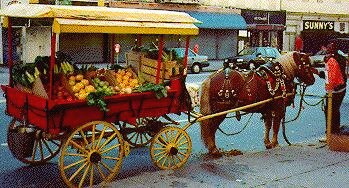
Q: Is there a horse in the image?
A: Yes, there is a horse.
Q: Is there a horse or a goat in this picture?
A: Yes, there is a horse.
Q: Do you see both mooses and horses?
A: No, there is a horse but no mooses.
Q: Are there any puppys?
A: No, there are no puppys.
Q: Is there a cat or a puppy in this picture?
A: No, there are no puppys or cats.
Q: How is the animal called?
A: The animal is a horse.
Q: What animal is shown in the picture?
A: The animal is a horse.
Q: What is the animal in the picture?
A: The animal is a horse.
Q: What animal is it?
A: The animal is a horse.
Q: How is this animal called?
A: This is a horse.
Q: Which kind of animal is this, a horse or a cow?
A: This is a horse.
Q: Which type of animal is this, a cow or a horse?
A: This is a horse.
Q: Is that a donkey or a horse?
A: That is a horse.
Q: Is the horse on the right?
A: Yes, the horse is on the right of the image.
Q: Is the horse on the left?
A: No, the horse is on the right of the image.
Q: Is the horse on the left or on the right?
A: The horse is on the right of the image.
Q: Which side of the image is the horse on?
A: The horse is on the right of the image.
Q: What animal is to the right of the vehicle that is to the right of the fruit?
A: The animal is a horse.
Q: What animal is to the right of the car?
A: The animal is a horse.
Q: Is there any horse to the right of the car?
A: Yes, there is a horse to the right of the car.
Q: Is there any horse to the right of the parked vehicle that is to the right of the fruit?
A: Yes, there is a horse to the right of the car.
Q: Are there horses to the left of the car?
A: No, the horse is to the right of the car.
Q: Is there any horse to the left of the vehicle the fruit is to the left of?
A: No, the horse is to the right of the car.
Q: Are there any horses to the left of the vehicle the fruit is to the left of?
A: No, the horse is to the right of the car.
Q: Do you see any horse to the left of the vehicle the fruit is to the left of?
A: No, the horse is to the right of the car.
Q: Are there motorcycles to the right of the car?
A: No, there is a horse to the right of the car.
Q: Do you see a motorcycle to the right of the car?
A: No, there is a horse to the right of the car.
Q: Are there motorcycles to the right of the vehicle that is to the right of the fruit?
A: No, there is a horse to the right of the car.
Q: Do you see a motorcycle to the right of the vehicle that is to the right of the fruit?
A: No, there is a horse to the right of the car.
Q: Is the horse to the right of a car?
A: Yes, the horse is to the right of a car.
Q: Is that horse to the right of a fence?
A: No, the horse is to the right of a car.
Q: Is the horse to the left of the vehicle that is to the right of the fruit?
A: No, the horse is to the right of the car.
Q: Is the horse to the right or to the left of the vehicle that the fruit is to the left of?
A: The horse is to the right of the car.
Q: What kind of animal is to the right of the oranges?
A: The animal is a horse.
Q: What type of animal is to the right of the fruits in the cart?
A: The animal is a horse.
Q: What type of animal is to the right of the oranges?
A: The animal is a horse.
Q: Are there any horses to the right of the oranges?
A: Yes, there is a horse to the right of the oranges.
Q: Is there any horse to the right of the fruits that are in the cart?
A: Yes, there is a horse to the right of the oranges.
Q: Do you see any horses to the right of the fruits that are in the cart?
A: Yes, there is a horse to the right of the oranges.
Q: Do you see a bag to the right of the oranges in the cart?
A: No, there is a horse to the right of the oranges.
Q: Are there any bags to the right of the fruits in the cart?
A: No, there is a horse to the right of the oranges.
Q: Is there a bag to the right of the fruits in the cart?
A: No, there is a horse to the right of the oranges.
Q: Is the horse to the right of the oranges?
A: Yes, the horse is to the right of the oranges.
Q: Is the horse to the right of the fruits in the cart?
A: Yes, the horse is to the right of the oranges.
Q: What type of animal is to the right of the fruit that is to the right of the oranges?
A: The animal is a horse.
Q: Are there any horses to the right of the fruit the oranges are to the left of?
A: Yes, there is a horse to the right of the fruit.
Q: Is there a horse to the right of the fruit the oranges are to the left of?
A: Yes, there is a horse to the right of the fruit.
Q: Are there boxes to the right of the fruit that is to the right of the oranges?
A: No, there is a horse to the right of the fruit.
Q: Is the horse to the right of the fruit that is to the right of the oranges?
A: Yes, the horse is to the right of the fruit.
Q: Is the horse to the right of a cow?
A: No, the horse is to the right of the fruit.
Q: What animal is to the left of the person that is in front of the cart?
A: The animal is a horse.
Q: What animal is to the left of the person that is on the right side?
A: The animal is a horse.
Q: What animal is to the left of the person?
A: The animal is a horse.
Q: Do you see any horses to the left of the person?
A: Yes, there is a horse to the left of the person.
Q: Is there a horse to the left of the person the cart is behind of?
A: Yes, there is a horse to the left of the person.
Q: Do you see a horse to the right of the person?
A: No, the horse is to the left of the person.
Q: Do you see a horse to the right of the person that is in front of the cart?
A: No, the horse is to the left of the person.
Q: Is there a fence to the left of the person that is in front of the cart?
A: No, there is a horse to the left of the person.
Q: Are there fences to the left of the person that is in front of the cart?
A: No, there is a horse to the left of the person.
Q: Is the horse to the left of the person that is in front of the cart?
A: Yes, the horse is to the left of the person.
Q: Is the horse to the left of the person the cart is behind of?
A: Yes, the horse is to the left of the person.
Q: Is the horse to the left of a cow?
A: No, the horse is to the left of the person.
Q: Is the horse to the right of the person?
A: No, the horse is to the left of the person.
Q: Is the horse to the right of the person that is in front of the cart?
A: No, the horse is to the left of the person.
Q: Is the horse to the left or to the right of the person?
A: The horse is to the left of the person.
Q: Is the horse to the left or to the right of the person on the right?
A: The horse is to the left of the person.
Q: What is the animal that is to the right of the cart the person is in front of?
A: The animal is a horse.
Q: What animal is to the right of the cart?
A: The animal is a horse.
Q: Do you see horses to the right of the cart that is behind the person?
A: Yes, there is a horse to the right of the cart.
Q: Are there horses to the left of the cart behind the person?
A: No, the horse is to the right of the cart.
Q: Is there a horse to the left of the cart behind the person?
A: No, the horse is to the right of the cart.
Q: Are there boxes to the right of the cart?
A: No, there is a horse to the right of the cart.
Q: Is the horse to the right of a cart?
A: Yes, the horse is to the right of a cart.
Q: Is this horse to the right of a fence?
A: No, the horse is to the right of a cart.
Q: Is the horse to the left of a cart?
A: No, the horse is to the right of a cart.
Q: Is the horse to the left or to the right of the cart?
A: The horse is to the right of the cart.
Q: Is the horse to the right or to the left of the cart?
A: The horse is to the right of the cart.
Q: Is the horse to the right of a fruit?
A: Yes, the horse is to the right of a fruit.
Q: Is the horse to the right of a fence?
A: No, the horse is to the right of a fruit.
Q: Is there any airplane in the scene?
A: No, there are no airplanes.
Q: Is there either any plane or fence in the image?
A: No, there are no airplanes or fences.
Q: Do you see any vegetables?
A: Yes, there are vegetables.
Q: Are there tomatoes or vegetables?
A: Yes, there are vegetables.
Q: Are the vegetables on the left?
A: Yes, the vegetables are on the left of the image.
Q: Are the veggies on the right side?
A: No, the veggies are on the left of the image.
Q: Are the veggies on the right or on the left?
A: The veggies are on the left of the image.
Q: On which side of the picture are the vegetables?
A: The vegetables are on the left of the image.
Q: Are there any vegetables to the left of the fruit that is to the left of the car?
A: Yes, there are vegetables to the left of the fruit.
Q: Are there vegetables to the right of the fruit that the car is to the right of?
A: No, the vegetables are to the left of the fruit.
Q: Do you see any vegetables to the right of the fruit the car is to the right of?
A: No, the vegetables are to the left of the fruit.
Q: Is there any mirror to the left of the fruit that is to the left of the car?
A: No, there are vegetables to the left of the fruit.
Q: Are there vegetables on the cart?
A: Yes, there are vegetables on the cart.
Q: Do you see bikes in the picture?
A: No, there are no bikes.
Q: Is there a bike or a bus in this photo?
A: No, there are no bikes or buses.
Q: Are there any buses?
A: No, there are no buses.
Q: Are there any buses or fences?
A: No, there are no buses or fences.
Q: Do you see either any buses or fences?
A: No, there are no buses or fences.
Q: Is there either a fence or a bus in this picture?
A: No, there are no buses or fences.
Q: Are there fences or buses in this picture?
A: No, there are no buses or fences.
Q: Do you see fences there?
A: No, there are no fences.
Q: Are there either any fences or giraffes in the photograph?
A: No, there are no fences or giraffes.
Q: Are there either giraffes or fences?
A: No, there are no fences or giraffes.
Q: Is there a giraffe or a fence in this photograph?
A: No, there are no fences or giraffes.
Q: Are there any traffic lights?
A: No, there are no traffic lights.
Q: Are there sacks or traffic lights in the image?
A: No, there are no traffic lights or sacks.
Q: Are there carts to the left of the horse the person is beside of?
A: Yes, there is a cart to the left of the horse.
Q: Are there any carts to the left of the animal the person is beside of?
A: Yes, there is a cart to the left of the horse.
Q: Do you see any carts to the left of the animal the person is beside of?
A: Yes, there is a cart to the left of the horse.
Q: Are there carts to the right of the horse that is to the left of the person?
A: No, the cart is to the left of the horse.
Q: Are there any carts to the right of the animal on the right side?
A: No, the cart is to the left of the horse.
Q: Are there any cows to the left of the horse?
A: No, there is a cart to the left of the horse.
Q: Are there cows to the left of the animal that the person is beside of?
A: No, there is a cart to the left of the horse.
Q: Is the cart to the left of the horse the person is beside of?
A: Yes, the cart is to the left of the horse.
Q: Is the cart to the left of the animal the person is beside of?
A: Yes, the cart is to the left of the horse.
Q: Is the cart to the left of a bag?
A: No, the cart is to the left of the horse.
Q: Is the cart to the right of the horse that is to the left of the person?
A: No, the cart is to the left of the horse.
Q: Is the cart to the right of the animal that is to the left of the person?
A: No, the cart is to the left of the horse.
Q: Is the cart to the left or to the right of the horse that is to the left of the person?
A: The cart is to the left of the horse.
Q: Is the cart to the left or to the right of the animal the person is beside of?
A: The cart is to the left of the horse.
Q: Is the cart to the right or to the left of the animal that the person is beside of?
A: The cart is to the left of the horse.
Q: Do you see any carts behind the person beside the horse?
A: Yes, there is a cart behind the person.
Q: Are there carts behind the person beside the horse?
A: Yes, there is a cart behind the person.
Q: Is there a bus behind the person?
A: No, there is a cart behind the person.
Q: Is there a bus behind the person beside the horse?
A: No, there is a cart behind the person.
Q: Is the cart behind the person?
A: Yes, the cart is behind the person.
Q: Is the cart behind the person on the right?
A: Yes, the cart is behind the person.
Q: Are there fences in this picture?
A: No, there are no fences.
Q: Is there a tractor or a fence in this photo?
A: No, there are no fences or tractors.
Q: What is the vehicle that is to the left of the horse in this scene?
A: The vehicle is a car.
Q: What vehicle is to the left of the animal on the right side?
A: The vehicle is a car.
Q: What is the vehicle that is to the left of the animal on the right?
A: The vehicle is a car.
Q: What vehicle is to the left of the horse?
A: The vehicle is a car.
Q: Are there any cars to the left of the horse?
A: Yes, there is a car to the left of the horse.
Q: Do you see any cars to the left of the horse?
A: Yes, there is a car to the left of the horse.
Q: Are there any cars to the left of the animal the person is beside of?
A: Yes, there is a car to the left of the horse.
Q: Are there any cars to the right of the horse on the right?
A: No, the car is to the left of the horse.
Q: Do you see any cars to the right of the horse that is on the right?
A: No, the car is to the left of the horse.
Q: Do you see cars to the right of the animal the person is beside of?
A: No, the car is to the left of the horse.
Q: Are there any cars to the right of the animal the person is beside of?
A: No, the car is to the left of the horse.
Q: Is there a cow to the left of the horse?
A: No, there is a car to the left of the horse.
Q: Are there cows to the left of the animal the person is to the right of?
A: No, there is a car to the left of the horse.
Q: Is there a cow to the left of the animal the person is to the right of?
A: No, there is a car to the left of the horse.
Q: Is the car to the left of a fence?
A: No, the car is to the left of a horse.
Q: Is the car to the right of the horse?
A: No, the car is to the left of the horse.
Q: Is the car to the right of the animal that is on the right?
A: No, the car is to the left of the horse.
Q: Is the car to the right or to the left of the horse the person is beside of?
A: The car is to the left of the horse.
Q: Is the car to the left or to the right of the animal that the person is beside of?
A: The car is to the left of the horse.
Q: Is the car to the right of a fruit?
A: Yes, the car is to the right of a fruit.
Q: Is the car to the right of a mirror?
A: No, the car is to the right of a fruit.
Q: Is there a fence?
A: No, there are no fences.